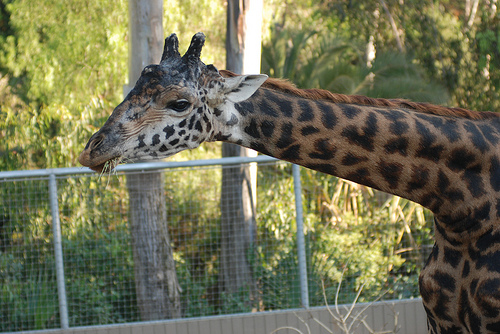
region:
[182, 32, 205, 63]
the horn on the head of the giraffe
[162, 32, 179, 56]
the horn on the head of the giraffe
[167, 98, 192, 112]
the eye on the head of the giraffe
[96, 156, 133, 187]
the grass in the mouth of the giraffe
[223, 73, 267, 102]
the ear on the head of the giraffe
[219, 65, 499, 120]
the mane on the back of the giraffe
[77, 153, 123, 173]
the giraffe's mouth slightly opened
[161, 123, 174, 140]
the dark brown spot on the giraffe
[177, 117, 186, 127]
the dark brown spot on the giraffe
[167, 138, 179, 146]
the dark brown spot on the giraffe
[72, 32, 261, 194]
the giraffe is eating.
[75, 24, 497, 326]
one giraffe is visible.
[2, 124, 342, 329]
the fence is silver.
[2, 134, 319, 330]
fence behind the giraffe.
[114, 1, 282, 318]
the tree trunk is brown.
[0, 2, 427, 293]
the leaves are green.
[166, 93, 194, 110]
the giraffes eye is black.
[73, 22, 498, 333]
the giraffe is brown.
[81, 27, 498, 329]
the giraffe is spotted.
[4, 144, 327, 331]
the fence is metal.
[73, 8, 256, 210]
the head of a giraffe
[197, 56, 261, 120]
the ear of a giraffe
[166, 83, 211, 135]
the eye of a giraffe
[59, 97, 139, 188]
the nose of a giraffe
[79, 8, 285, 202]
the face of a giraffe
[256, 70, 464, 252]
the neck of a giraffe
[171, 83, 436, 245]
a brown spotted giraffe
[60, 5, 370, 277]
a giraffe near a fence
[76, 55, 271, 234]
a giraffe near a tree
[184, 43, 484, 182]
the main of a giraffe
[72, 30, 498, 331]
brown giraffe with dark brown spots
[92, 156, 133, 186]
giraffe's mouth full of straw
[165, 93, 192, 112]
shiny black giraffe eye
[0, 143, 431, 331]
tall metal wire fence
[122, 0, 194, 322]
tall tan tree trunk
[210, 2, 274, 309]
tall tan tree trunk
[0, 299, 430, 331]
concrete fence base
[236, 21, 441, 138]
green palm fronds atop a tree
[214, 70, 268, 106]
little white giraffe ear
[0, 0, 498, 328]
dense green foliage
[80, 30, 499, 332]
Giraffe is eating hay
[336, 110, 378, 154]
Brown spot on giraffe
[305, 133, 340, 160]
Brown spot on giraffe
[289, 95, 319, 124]
Brown spot on giraffe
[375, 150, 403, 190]
Brown spot on giraffe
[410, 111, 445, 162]
Brown spot on giraffe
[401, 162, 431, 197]
Brown spot on giraffe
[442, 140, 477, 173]
Brown spot on giraffe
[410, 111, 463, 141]
Brown spot on giraffe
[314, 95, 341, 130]
Brown spot on giraffe